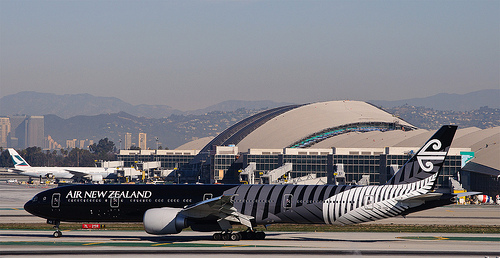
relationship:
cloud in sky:
[195, 45, 257, 75] [3, 1, 497, 146]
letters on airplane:
[64, 192, 152, 198] [21, 124, 483, 242]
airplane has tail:
[25, 120, 464, 236] [390, 120, 462, 176]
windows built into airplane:
[282, 193, 293, 208] [22, 122, 482, 241]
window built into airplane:
[328, 198, 332, 203] [22, 122, 482, 241]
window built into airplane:
[335, 199, 339, 203] [22, 122, 482, 241]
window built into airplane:
[341, 199, 344, 203] [22, 122, 482, 241]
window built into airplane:
[348, 200, 352, 204] [22, 122, 482, 241]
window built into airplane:
[294, 198, 298, 202] [25, 120, 464, 236]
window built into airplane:
[303, 198, 307, 203] [25, 120, 464, 236]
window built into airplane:
[308, 198, 312, 202] [25, 120, 464, 236]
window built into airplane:
[312, 199, 316, 203] [25, 120, 464, 236]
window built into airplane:
[299, 198, 304, 204] [25, 120, 464, 236]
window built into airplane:
[322, 199, 325, 202] [25, 120, 464, 236]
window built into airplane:
[325, 199, 329, 203] [25, 120, 464, 236]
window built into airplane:
[332, 199, 335, 203] [25, 120, 464, 236]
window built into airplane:
[342, 201, 343, 203] [25, 120, 464, 236]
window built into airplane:
[348, 200, 352, 204] [25, 120, 464, 236]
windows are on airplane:
[203, 193, 213, 201] [25, 120, 464, 236]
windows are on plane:
[203, 193, 213, 201] [19, 122, 473, 240]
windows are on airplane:
[137, 195, 177, 203] [25, 120, 464, 236]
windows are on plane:
[249, 193, 282, 208] [19, 122, 473, 240]